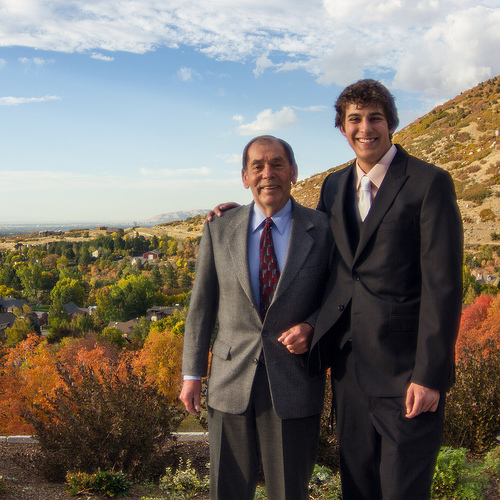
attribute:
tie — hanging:
[256, 217, 282, 322]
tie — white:
[358, 175, 373, 220]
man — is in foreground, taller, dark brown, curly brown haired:
[306, 76, 466, 498]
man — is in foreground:
[176, 130, 336, 497]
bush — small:
[13, 353, 185, 480]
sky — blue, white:
[51, 31, 308, 168]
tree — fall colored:
[31, 334, 211, 468]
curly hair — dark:
[332, 75, 403, 127]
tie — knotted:
[346, 171, 407, 225]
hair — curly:
[331, 70, 409, 132]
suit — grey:
[339, 156, 465, 363]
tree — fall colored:
[2, 343, 199, 493]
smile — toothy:
[354, 132, 379, 145]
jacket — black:
[188, 197, 319, 374]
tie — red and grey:
[257, 212, 281, 312]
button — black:
[333, 299, 344, 319]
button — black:
[349, 271, 365, 283]